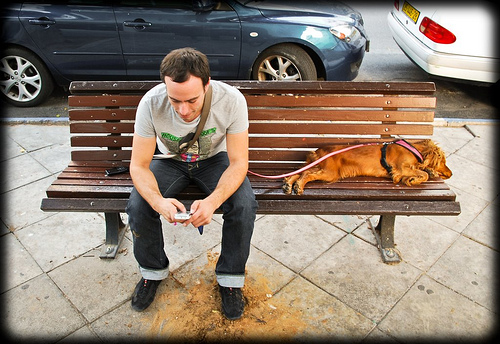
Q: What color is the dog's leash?
A: Pink.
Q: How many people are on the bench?
A: One.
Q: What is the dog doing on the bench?
A: Sleeping.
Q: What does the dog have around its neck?
A: A pink leash harness.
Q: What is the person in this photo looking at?
A: A cell phone.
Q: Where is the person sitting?
A: On a bench.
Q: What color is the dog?
A: Brown.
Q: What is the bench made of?
A: Wooden slats.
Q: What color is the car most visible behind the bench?
A: Blue.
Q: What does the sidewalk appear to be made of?
A: Concrete.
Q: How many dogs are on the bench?
A: One.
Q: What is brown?
A: Dog.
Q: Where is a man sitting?
A: On the bench.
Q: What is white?
A: A car.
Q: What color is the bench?
A: Brown.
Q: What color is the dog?
A: Brown.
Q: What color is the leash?
A: Red and white.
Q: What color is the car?
A: White.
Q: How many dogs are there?
A: One.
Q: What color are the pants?
A: Black.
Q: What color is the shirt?
A: White.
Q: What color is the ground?
A: Gray.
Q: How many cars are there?
A: Two.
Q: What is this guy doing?
A: Sitting on the bench.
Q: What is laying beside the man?
A: Dog.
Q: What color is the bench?
A: Brown.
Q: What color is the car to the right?
A: White.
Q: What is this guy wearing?
A: Jeans.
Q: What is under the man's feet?
A: Dirt.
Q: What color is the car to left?
A: Blue.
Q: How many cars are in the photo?
A: 2.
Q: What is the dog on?
A: Leash.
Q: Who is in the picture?
A: A man.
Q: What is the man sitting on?
A: A bench.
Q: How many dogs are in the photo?
A: One.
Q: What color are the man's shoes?
A: Black.